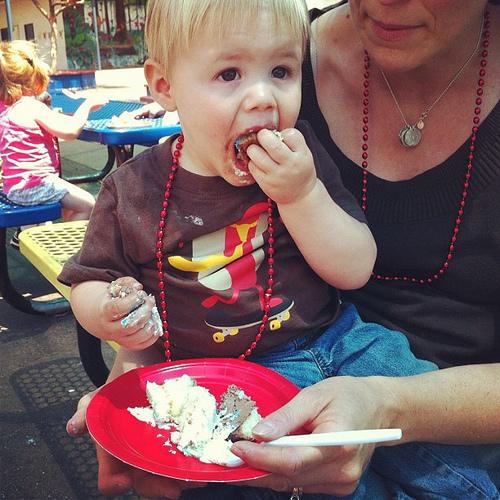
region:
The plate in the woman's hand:
[77, 373, 356, 488]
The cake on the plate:
[140, 381, 262, 461]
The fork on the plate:
[233, 427, 409, 450]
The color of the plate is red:
[90, 398, 197, 485]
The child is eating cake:
[94, 4, 420, 483]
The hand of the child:
[241, 120, 321, 206]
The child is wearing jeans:
[241, 295, 495, 498]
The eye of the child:
[199, 52, 246, 92]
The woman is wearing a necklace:
[373, 38, 484, 158]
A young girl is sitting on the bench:
[2, 30, 117, 232]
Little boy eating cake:
[138, 43, 323, 212]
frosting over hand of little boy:
[100, 257, 180, 342]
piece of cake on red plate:
[140, 374, 285, 470]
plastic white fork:
[256, 415, 403, 462]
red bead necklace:
[157, 186, 310, 352]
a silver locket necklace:
[376, 95, 454, 176]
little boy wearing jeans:
[286, 347, 488, 492]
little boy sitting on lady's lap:
[72, 13, 497, 495]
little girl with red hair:
[13, 34, 100, 216]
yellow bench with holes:
[23, 223, 117, 350]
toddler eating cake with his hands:
[75, 5, 467, 482]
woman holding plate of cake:
[87, 4, 496, 488]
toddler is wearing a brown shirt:
[72, 7, 374, 381]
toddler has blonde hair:
[62, 0, 379, 365]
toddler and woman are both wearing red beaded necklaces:
[63, 0, 497, 422]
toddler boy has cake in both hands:
[54, 4, 388, 351]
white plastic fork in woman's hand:
[212, 386, 399, 487]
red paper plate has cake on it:
[75, 351, 322, 488]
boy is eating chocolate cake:
[66, 3, 386, 371]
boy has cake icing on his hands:
[59, 1, 391, 374]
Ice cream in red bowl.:
[99, 359, 294, 479]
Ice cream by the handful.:
[97, 273, 263, 435]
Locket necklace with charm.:
[380, 77, 445, 154]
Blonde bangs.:
[167, 8, 304, 55]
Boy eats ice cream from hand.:
[175, 56, 311, 197]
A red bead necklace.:
[355, 73, 492, 295]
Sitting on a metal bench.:
[0, 33, 87, 219]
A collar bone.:
[308, 24, 383, 109]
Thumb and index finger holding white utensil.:
[228, 371, 361, 478]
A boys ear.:
[140, 54, 182, 115]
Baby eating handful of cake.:
[53, 4, 441, 403]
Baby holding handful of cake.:
[101, 274, 169, 354]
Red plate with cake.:
[86, 355, 311, 487]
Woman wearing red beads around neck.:
[348, 5, 490, 290]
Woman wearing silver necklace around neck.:
[366, 10, 496, 146]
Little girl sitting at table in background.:
[2, 35, 117, 227]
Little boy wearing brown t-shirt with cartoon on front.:
[48, 116, 379, 353]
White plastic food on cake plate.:
[205, 421, 405, 463]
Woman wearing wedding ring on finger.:
[288, 481, 311, 497]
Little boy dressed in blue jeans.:
[240, 304, 499, 496]